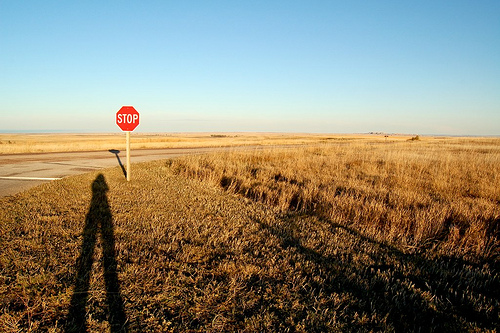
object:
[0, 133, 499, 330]
ground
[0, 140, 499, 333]
field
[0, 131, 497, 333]
grass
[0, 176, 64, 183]
line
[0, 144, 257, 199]
street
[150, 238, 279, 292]
shadow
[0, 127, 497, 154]
grass field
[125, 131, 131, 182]
pole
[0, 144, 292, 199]
road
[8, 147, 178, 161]
dirt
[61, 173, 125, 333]
shadow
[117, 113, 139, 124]
word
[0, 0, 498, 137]
sky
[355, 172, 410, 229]
hay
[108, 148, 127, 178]
shadow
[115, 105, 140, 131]
sign